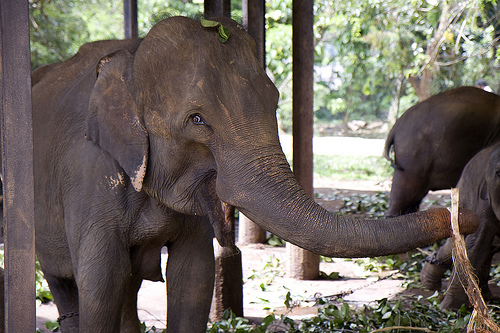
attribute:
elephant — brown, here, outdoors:
[31, 14, 477, 331]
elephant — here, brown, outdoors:
[381, 86, 499, 218]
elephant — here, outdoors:
[416, 141, 499, 310]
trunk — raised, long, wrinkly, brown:
[217, 147, 482, 258]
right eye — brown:
[188, 112, 210, 126]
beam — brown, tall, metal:
[2, 1, 35, 332]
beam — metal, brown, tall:
[293, 0, 317, 279]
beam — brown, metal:
[238, 0, 267, 242]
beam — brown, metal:
[203, 0, 243, 325]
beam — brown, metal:
[122, 0, 138, 41]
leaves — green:
[32, 0, 499, 129]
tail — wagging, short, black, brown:
[381, 130, 404, 174]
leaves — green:
[195, 293, 499, 332]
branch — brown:
[409, 4, 456, 97]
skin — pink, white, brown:
[129, 154, 149, 193]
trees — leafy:
[31, 2, 500, 134]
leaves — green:
[197, 15, 233, 43]